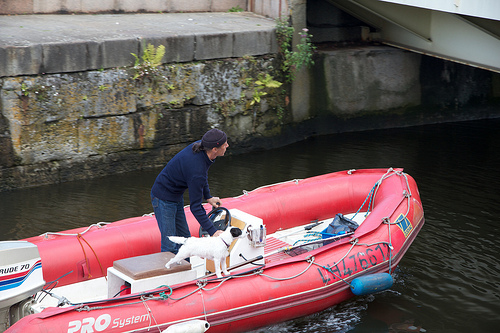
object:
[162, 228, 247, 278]
dog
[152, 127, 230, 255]
man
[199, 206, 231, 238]
wheel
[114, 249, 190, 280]
cushion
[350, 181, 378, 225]
rope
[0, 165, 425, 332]
boat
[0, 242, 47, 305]
engine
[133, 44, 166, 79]
weeds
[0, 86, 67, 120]
mold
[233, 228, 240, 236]
ear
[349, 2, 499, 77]
bridge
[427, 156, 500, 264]
water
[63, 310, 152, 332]
writing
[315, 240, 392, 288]
number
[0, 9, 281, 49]
platform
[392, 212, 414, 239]
sign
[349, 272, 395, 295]
buoy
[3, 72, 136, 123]
brick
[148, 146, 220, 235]
sweater